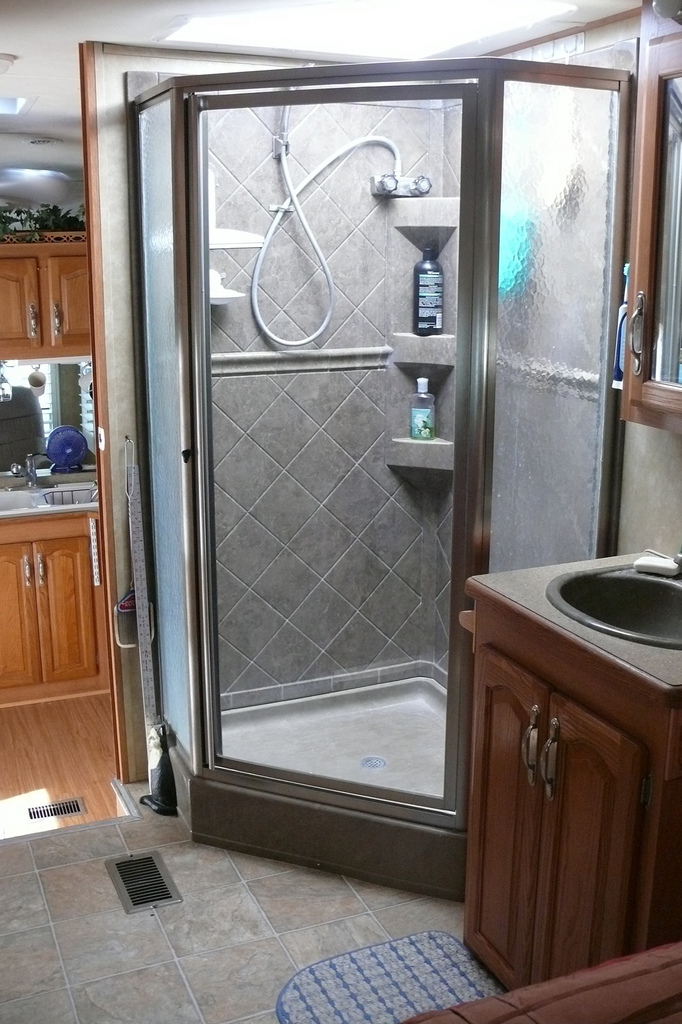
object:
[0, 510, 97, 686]
cabinets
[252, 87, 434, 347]
shower head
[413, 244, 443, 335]
bottle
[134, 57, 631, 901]
shower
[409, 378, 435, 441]
bottle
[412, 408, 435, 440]
label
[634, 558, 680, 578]
soap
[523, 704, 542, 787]
handle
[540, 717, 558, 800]
handle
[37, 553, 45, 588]
handle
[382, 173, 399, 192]
knobs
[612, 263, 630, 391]
toothbrush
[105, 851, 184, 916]
vent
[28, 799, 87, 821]
vent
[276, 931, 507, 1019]
mat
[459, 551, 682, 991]
base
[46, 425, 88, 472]
fan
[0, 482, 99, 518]
sink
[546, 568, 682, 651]
sink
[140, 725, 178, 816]
decoration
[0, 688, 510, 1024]
bathroom floor